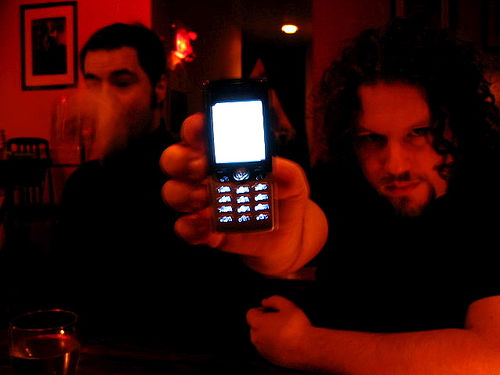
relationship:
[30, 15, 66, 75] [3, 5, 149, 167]
photograph hanging on wall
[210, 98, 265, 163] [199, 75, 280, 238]
display on a illuminated smartphone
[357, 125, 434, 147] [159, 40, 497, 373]
eyes of man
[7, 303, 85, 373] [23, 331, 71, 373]
glass filled with liquid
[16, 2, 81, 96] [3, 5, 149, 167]
picture frame on wall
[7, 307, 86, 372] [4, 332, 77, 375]
glass filled with liquid